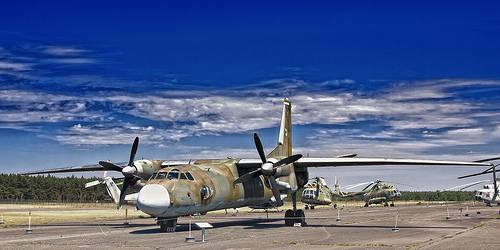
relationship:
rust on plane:
[19, 98, 498, 228] [196, 183, 216, 208]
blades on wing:
[242, 139, 303, 199] [240, 155, 495, 178]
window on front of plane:
[153, 172, 166, 180] [196, 183, 216, 208]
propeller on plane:
[99, 137, 150, 209] [196, 183, 216, 208]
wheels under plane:
[284, 207, 304, 226] [196, 183, 216, 208]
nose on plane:
[138, 182, 168, 214] [196, 183, 216, 208]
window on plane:
[153, 172, 166, 180] [196, 183, 216, 208]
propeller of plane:
[99, 137, 150, 209] [196, 183, 216, 208]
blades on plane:
[242, 139, 303, 199] [196, 183, 216, 208]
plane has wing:
[196, 183, 216, 208] [240, 155, 495, 178]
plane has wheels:
[196, 183, 216, 208] [162, 224, 173, 231]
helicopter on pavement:
[307, 175, 338, 207] [12, 207, 498, 250]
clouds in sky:
[133, 88, 277, 133] [3, 1, 497, 193]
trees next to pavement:
[3, 175, 95, 201] [12, 207, 498, 250]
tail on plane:
[266, 100, 293, 158] [196, 183, 216, 208]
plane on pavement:
[196, 183, 216, 208] [12, 207, 498, 250]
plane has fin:
[196, 183, 216, 208] [319, 152, 355, 159]